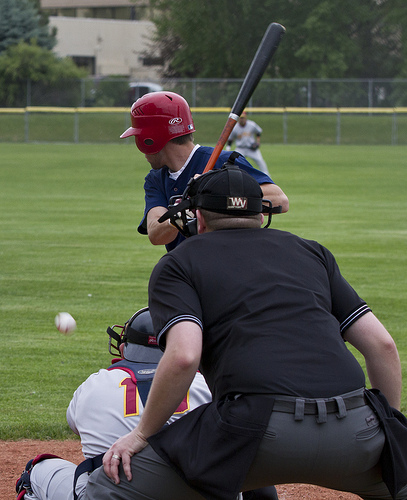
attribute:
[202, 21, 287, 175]
bat — colored, black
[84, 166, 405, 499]
umpire — watching, working, bending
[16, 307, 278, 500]
catcher — squatting, crouching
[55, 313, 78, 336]
baseball — white, flying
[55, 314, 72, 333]
stitching — red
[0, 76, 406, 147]
fence — gray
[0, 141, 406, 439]
grass — green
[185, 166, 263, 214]
cap — black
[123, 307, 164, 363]
helmet — blue, red, black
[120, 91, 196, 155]
helmet — red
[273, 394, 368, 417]
belt — black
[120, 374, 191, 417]
number — red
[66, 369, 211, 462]
jersey — colored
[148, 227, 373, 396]
shirt — black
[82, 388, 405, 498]
pants — gray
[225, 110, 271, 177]
player — playing, dressed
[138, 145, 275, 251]
top — blue